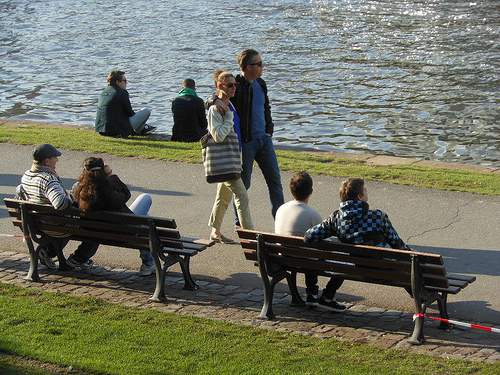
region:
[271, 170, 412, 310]
two man sitting on bench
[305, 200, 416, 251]
black and blue plaid sweater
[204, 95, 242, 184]
gray and white purse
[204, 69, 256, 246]
woman walking on sidewalk with sand pats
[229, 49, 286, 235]
man walking on sidewalk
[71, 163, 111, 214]
large dark hair of woman in bench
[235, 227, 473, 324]
brown wooden bench in the right side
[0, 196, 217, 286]
brown wooden bench in the left side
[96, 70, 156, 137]
man sitting next to lake wearing green sweater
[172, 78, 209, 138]
man sitting next to the lake wearing black jacket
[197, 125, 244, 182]
oversized striped bag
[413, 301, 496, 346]
red and white tape to block area of park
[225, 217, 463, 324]
wood slatted park bench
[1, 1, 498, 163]
ripples in the water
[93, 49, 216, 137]
peopel sit at the erdge of the water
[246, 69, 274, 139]
man wears a blue shirt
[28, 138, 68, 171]
man sitting on bench wears a cap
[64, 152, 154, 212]
girl sitting has long brown hair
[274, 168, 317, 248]
man wearing a white shirt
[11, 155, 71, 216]
man wears a striped jacket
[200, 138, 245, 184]
a women carrying a purse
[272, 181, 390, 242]
two people setting on a bench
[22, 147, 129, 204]
a man and a women sitting on the bench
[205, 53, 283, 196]
two people walking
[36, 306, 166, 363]
a row of grass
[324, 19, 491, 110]
the water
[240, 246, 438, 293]
a brown bench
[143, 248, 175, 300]
leg of the bench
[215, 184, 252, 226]
the women is wearing pants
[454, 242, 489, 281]
a shadow on the ground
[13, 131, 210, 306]
people are sitting on the bench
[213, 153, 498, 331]
people are sitting on the bench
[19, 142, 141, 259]
people are sitting on the bench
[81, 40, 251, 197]
two people sitting on the grass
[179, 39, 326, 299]
a couple walking at the park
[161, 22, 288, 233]
a couple walking at the park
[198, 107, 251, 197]
the bag is stripes